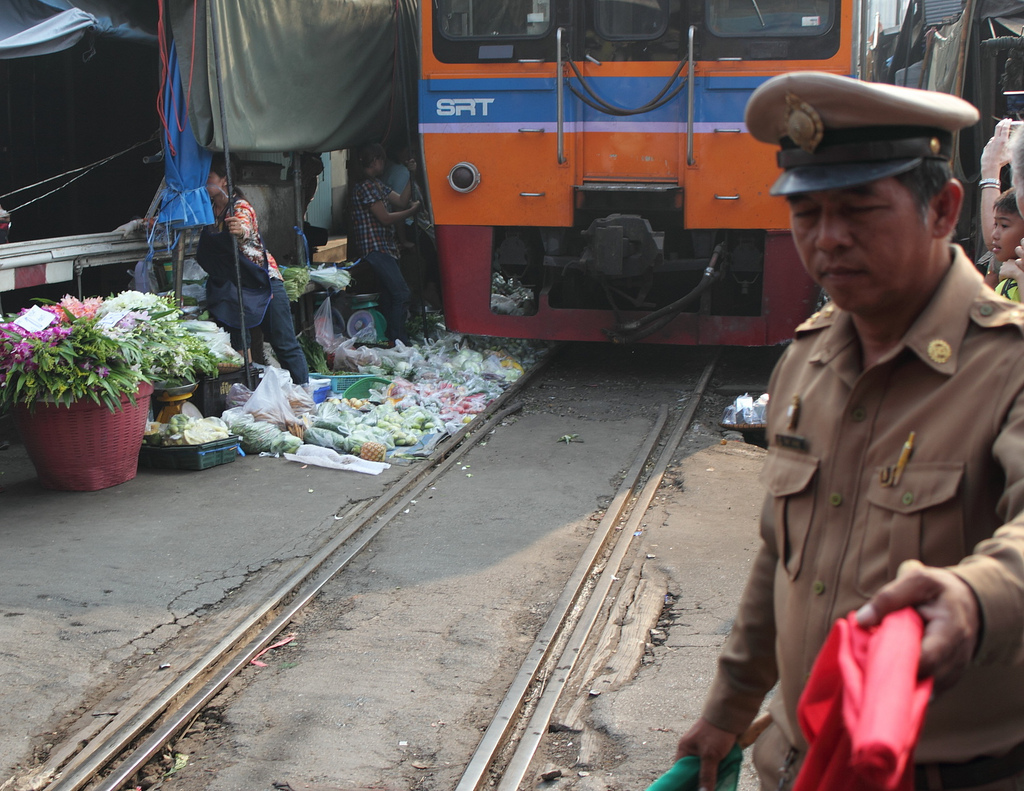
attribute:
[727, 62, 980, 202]
hat — tan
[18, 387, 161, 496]
pot — red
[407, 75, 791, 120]
stripe — blue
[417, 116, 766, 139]
stripe — white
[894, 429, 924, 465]
pen — gold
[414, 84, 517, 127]
srt — letters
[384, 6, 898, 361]
train — stopped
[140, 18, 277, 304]
parasol — blue, closed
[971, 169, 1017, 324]
child — standing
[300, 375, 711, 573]
train tracks — metal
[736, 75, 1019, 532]
uniform — brown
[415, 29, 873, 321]
orange train — blue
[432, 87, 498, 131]
lettering — white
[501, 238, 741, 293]
bars — metal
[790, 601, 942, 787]
flag — red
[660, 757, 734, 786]
flag — green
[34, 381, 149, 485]
flower basket — red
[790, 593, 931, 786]
flag — red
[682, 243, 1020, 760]
uniform — tan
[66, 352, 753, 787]
tracks — train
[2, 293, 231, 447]
flowers — purple, white, pink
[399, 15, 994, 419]
train — blue, orange